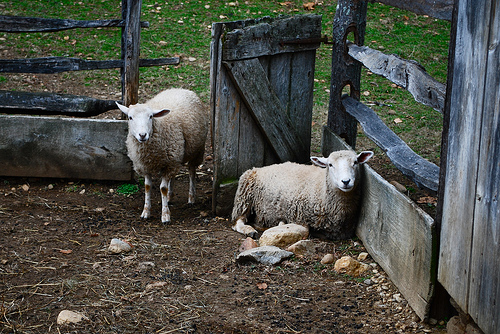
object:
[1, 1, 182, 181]
pen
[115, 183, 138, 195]
plants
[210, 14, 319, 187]
door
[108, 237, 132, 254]
rocks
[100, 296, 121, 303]
straw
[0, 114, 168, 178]
ground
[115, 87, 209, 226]
sheep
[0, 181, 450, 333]
dirt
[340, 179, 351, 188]
black nose